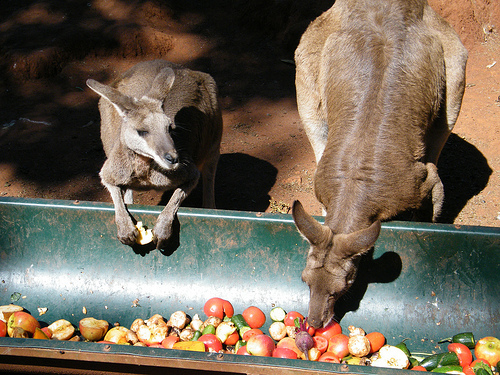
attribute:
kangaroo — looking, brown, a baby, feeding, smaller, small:
[85, 58, 222, 253]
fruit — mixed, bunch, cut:
[133, 221, 156, 247]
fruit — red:
[8, 312, 39, 340]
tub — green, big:
[2, 196, 500, 374]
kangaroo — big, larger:
[287, 1, 469, 330]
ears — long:
[86, 78, 138, 121]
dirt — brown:
[3, 1, 498, 233]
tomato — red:
[311, 333, 328, 354]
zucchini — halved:
[438, 332, 476, 347]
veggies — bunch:
[177, 292, 313, 352]